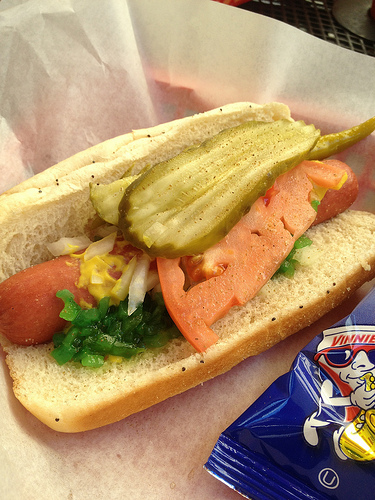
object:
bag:
[202, 286, 375, 498]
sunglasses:
[314, 343, 374, 367]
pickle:
[120, 117, 375, 258]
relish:
[56, 283, 177, 367]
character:
[297, 320, 374, 461]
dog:
[0, 158, 359, 347]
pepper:
[238, 221, 283, 266]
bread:
[0, 100, 375, 434]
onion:
[83, 230, 117, 260]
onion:
[90, 274, 103, 284]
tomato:
[156, 161, 347, 354]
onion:
[127, 255, 151, 316]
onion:
[47, 235, 93, 258]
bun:
[0, 99, 372, 435]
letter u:
[320, 467, 337, 490]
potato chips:
[202, 294, 375, 500]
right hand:
[350, 382, 374, 411]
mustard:
[82, 258, 111, 294]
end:
[0, 272, 47, 344]